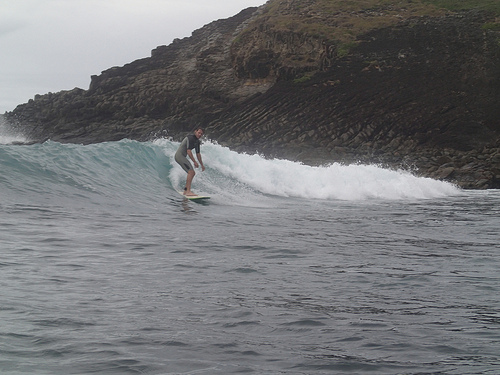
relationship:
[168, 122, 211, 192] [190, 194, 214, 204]
man riding surfboard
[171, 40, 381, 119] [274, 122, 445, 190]
rocks on shore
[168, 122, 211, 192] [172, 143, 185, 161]
man slightly bent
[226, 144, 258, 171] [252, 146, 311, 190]
crest of a wave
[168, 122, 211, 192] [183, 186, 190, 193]
man wears leg strap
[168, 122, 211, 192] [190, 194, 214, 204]
man on surfboard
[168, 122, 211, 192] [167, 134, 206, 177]
man wearing wet suit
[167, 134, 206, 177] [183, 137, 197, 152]
wet suit has sleeves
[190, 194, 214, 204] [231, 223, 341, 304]
surfboard in water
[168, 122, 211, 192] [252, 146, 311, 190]
surfer riding wave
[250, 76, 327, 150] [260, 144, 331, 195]
rock by seaside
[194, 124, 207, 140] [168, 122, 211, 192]
head of surfer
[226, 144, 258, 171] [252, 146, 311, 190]
crest of wave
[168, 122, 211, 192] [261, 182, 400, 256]
man surfing in ocean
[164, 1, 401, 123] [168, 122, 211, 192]
mountain behind surfer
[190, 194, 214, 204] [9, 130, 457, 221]
surboard at bottom wave